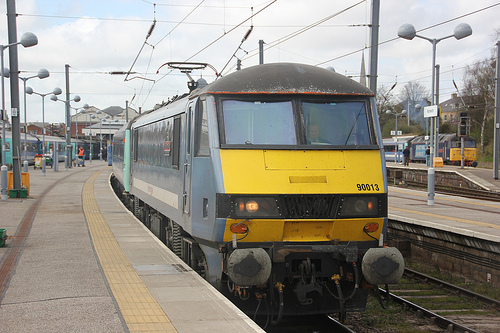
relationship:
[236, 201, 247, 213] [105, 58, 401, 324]
light on train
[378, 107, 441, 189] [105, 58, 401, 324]
man waits for train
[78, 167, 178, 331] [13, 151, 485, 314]
yellow brick along platform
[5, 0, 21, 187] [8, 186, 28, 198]
pole supported by base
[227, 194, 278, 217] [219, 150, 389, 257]
headlight on front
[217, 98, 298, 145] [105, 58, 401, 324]
window on train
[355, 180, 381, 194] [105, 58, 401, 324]
number on train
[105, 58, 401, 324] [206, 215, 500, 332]
train on track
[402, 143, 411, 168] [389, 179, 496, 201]
person standing on track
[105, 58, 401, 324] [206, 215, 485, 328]
train on track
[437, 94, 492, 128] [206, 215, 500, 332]
brick building next to train track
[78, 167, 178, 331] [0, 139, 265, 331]
yellow brick on sidewalk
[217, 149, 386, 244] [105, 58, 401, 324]
paint on train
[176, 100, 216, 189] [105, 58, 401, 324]
window on train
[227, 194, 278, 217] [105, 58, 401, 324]
headlight on train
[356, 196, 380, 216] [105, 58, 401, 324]
headlight on train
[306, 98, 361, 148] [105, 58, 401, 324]
conductor in train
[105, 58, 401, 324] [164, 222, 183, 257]
train has wheel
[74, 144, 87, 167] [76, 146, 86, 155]
man wears orange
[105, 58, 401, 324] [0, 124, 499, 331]
train in station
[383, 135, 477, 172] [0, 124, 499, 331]
train in station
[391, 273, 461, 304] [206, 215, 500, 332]
grass growing on track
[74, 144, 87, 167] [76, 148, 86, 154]
man wearing jacket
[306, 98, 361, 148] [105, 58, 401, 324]
conductor sitting in train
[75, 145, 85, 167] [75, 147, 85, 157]
person wearing orange vest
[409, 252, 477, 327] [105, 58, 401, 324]
railroad tracks to right of train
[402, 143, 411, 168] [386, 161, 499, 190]
person standing on platform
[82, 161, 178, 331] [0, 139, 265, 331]
line on sidewalk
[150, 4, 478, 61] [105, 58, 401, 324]
wires above train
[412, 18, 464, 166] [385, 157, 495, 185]
street lights on sidewalk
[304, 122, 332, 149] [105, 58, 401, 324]
driver sits in train